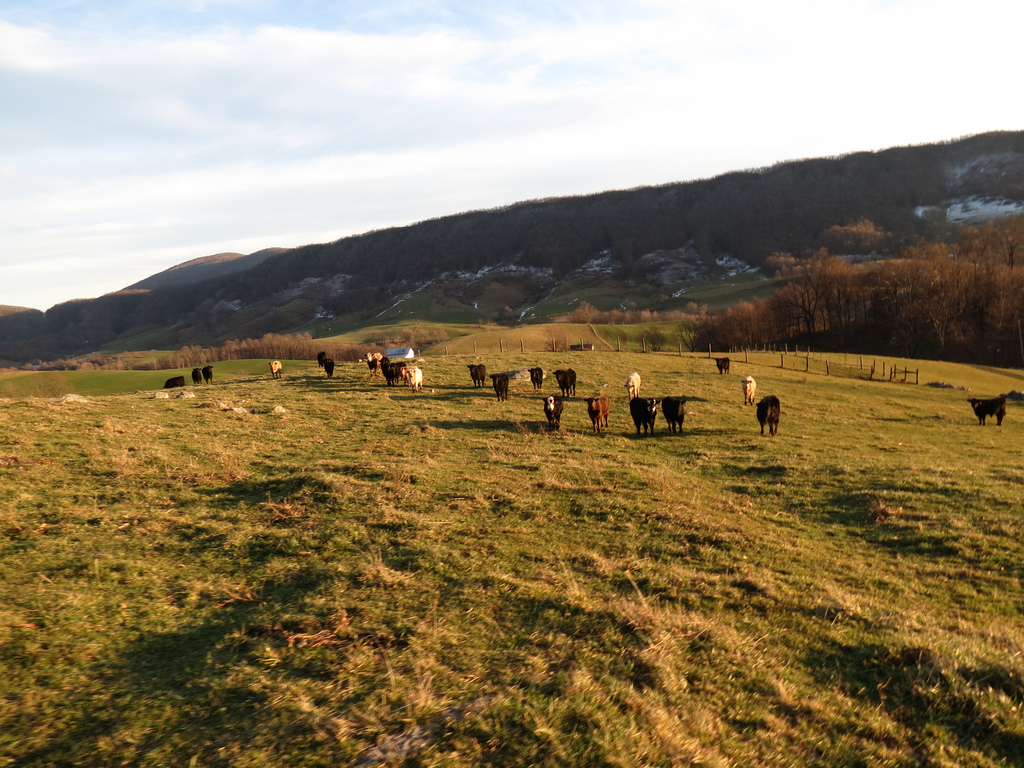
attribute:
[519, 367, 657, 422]
cows — scattered, herd, standing, adult, grazing, light, dark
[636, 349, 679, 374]
hillside — curving, shadowed, large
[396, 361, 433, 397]
cow — black, lonely, brown, alone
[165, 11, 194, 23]
sky — blue, sunny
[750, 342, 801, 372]
fence — wooden, small, background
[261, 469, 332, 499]
grass — green, dead, hay, clumped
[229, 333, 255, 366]
brush — tall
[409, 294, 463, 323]
trees — bare, large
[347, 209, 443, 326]
hills — rolling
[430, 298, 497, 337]
vegetation — dry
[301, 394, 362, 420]
pasture — green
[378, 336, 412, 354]
building — white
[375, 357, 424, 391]
cattle — grazing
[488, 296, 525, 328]
treeline — dormant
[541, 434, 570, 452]
manure — piled